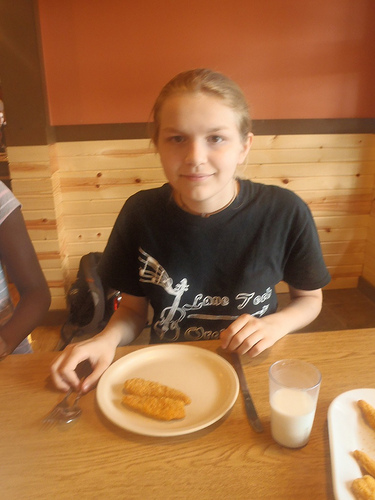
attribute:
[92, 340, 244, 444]
plate — round, white, tan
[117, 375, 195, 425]
chicken tenders — pair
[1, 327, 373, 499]
table — wooden, wood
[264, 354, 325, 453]
glass — half full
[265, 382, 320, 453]
milk — white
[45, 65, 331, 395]
girl — smiling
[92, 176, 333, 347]
shirt — black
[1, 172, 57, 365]
person — sitting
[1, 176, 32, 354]
shirt — grey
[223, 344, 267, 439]
knife — metal, left of plate, resting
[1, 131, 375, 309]
wall — wood, wooden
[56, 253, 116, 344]
backpack — gray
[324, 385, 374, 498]
platter — white